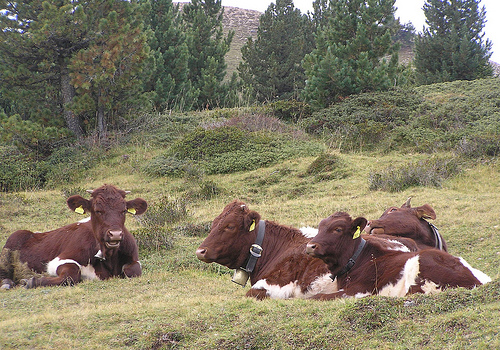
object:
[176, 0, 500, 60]
sky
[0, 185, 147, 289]
cow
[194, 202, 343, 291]
cow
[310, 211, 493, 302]
cow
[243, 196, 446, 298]
cow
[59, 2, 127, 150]
trees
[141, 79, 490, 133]
hills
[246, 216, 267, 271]
collar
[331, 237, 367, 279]
collar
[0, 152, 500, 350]
grass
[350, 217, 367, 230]
ear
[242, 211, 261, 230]
ear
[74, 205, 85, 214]
tag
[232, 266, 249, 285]
bell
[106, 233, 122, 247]
mouth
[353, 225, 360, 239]
tag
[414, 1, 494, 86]
trees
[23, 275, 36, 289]
hoof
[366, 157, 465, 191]
brush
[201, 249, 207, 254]
nostril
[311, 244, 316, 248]
nostril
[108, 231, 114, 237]
nose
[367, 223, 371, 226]
nose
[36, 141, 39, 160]
stem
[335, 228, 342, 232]
eye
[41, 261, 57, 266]
hair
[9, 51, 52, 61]
branches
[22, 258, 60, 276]
stomach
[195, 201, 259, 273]
head